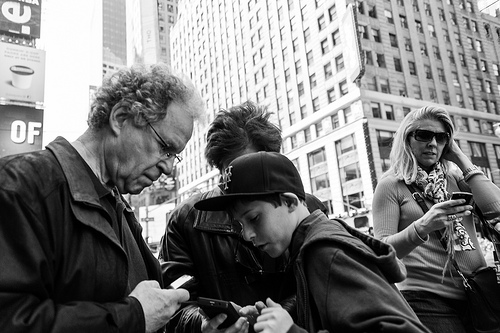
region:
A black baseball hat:
[193, 146, 318, 213]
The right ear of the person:
[105, 96, 137, 140]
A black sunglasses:
[406, 125, 455, 147]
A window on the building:
[329, 29, 342, 49]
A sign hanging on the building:
[334, 1, 368, 86]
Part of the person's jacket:
[10, 195, 62, 264]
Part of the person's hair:
[219, 122, 249, 137]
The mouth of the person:
[138, 168, 160, 187]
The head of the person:
[71, 56, 207, 198]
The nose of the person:
[238, 213, 258, 242]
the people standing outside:
[0, 63, 497, 331]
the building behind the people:
[82, 1, 498, 267]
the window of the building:
[337, 79, 347, 98]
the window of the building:
[383, 7, 394, 24]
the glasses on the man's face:
[137, 109, 182, 165]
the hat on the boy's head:
[192, 154, 306, 209]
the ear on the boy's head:
[283, 192, 298, 213]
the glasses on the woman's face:
[408, 126, 450, 143]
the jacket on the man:
[2, 137, 164, 332]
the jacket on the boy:
[286, 217, 431, 332]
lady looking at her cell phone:
[367, 105, 498, 330]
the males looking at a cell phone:
[2, 64, 430, 331]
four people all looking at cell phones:
[1, 65, 498, 331]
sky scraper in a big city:
[169, 1, 497, 233]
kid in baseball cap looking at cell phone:
[193, 152, 426, 332]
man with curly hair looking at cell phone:
[1, 65, 256, 330]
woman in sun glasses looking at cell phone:
[371, 102, 497, 332]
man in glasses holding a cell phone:
[1, 65, 201, 328]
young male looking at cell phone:
[194, 150, 434, 332]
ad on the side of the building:
[1, 0, 44, 165]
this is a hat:
[185, 151, 308, 208]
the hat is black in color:
[245, 158, 270, 180]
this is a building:
[210, 13, 474, 83]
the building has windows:
[240, 29, 322, 64]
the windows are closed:
[244, 18, 325, 65]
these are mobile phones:
[165, 266, 230, 310]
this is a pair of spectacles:
[116, 106, 186, 162]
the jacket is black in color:
[3, 204, 63, 264]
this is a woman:
[359, 102, 496, 321]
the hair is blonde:
[396, 153, 413, 173]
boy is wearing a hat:
[196, 153, 293, 204]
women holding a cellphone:
[450, 191, 472, 201]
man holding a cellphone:
[169, 276, 196, 286]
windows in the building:
[326, 80, 352, 100]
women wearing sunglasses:
[414, 128, 449, 140]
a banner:
[1, 41, 47, 98]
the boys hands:
[252, 301, 295, 331]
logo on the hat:
[213, 166, 240, 188]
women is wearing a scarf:
[423, 178, 448, 197]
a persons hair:
[209, 106, 271, 146]